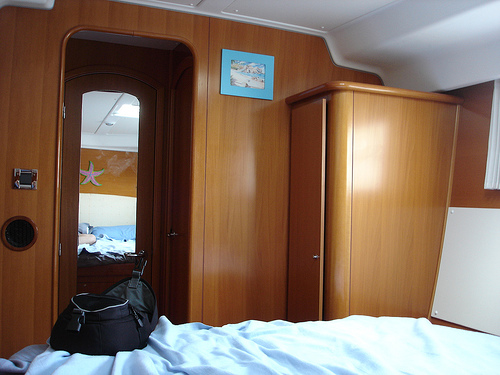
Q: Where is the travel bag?
A: On the bed.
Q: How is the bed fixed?
A: Not made up.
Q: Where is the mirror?
A: On door.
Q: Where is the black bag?
A: On bed.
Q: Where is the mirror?
A: Across the bed.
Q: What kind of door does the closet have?
A: Open.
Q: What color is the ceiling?
A: White.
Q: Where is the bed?
A: In a bathroom.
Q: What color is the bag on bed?
A: Black.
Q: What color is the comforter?
A: White.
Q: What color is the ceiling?
A: White.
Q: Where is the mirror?
A: On closet.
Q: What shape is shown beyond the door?
A: A Star.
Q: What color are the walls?
A: Brown.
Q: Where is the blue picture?
A: On the wall.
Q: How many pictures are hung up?
A: Two.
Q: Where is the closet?
A: Right of the doorway.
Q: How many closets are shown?
A: One.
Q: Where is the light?
A: Beyond the door.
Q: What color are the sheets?
A: White.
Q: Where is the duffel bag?
A: On the bed.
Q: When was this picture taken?
A: On vacation.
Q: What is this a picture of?
A: The interior of an RV.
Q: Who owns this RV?
A: Bob and Sally.